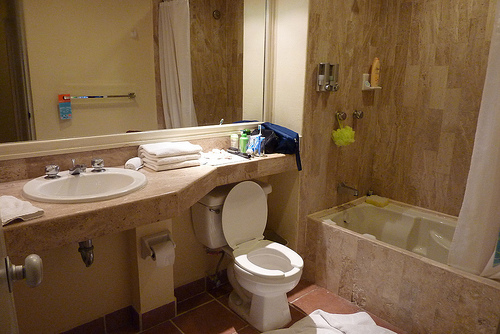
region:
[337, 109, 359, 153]
A sponge on the handle.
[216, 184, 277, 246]
The toilet seat is up.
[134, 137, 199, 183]
White towels on the counter.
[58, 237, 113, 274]
Pipes under the sink.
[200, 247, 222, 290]
Pipes in the back of the toilet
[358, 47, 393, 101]
Shampoo in the shower.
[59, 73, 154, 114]
A towel rack on the wall.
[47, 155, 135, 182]
Faucet on the sink.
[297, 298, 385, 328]
White towel on the floor.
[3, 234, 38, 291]
The door knob of the bathroom door.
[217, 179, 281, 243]
toilet lid is up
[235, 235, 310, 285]
toilet seat is down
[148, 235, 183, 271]
a roll of toilet paper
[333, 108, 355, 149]
loofah hanging in the tub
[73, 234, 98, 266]
pipe under the sink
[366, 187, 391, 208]
sponge on the corner of the tub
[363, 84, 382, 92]
small white shelf on the shower wall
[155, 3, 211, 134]
white shower curtain pushed to one side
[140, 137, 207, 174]
a stack of folded towels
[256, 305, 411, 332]
white towel on the floor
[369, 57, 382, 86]
Pink bottle in a shower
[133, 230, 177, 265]
Toilet paper on a roll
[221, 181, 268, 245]
Toilet lid up on a toilet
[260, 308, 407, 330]
White towel on the ground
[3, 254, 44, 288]
Handel on a door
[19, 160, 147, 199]
Sink on a counter top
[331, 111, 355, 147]
Yellow luff-ah in a bathtub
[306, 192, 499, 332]
Bathtub in a bathroom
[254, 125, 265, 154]
Blue toothbrush on a counter top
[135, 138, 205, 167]
White towels stacked on a countertop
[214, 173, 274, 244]
toilet lid made out of white porcelain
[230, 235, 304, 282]
toilet seat made out of white porcelain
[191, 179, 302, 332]
toilet made out of white porcelain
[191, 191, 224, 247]
toilet tank made out of white porcelain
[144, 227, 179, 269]
white toilet paper roll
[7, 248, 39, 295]
silver knob of bathroom door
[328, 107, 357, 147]
yellow spongy hanging from the wall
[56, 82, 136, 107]
reflection of towel rack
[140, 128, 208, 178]
pile of towles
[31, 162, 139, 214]
sink made out of white porcelain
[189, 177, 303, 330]
the toilet in the bathroom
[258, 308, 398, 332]
the towel on the ground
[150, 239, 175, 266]
the roll of toilet paper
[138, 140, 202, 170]
the folded towels on the counter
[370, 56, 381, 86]
the plastic bottle in the shower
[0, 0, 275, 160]
the mirror on the wall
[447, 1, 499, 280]
the shower curtain hanging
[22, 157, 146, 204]
the sink in the bathroom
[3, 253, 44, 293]
the knob on the door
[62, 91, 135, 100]
the towel bar on the wall